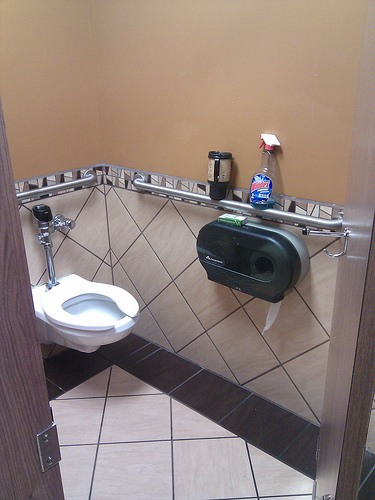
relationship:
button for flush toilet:
[32, 203, 52, 221] [29, 200, 139, 356]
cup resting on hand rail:
[207, 151, 235, 200] [133, 169, 341, 225]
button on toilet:
[32, 203, 52, 221] [29, 201, 139, 355]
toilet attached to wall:
[28, 272, 139, 354] [0, 0, 111, 402]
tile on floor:
[163, 367, 245, 424] [39, 331, 312, 498]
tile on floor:
[126, 345, 203, 390] [39, 331, 312, 498]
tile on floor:
[219, 392, 321, 479] [39, 331, 312, 498]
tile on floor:
[101, 329, 163, 369] [39, 331, 312, 498]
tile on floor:
[40, 347, 106, 392] [39, 331, 312, 498]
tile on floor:
[168, 392, 245, 439] [39, 331, 312, 498]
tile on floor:
[245, 439, 314, 496] [39, 331, 312, 498]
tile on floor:
[172, 437, 259, 499] [39, 331, 312, 498]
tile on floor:
[87, 437, 173, 497] [39, 331, 312, 498]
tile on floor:
[54, 441, 98, 498] [39, 331, 312, 498]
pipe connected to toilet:
[31, 214, 75, 284] [28, 272, 139, 354]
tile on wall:
[238, 363, 317, 422] [99, 168, 338, 431]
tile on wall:
[289, 235, 344, 337] [99, 168, 338, 431]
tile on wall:
[241, 288, 329, 365] [99, 168, 338, 431]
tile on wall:
[139, 199, 203, 278] [99, 168, 338, 431]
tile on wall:
[146, 280, 206, 352] [99, 168, 338, 431]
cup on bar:
[207, 151, 235, 200] [131, 176, 343, 232]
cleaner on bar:
[249, 128, 280, 210] [131, 176, 343, 232]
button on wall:
[32, 203, 53, 221] [0, 0, 114, 363]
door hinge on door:
[35, 422, 62, 471] [0, 106, 67, 496]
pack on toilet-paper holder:
[218, 213, 247, 227] [195, 217, 313, 303]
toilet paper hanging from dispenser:
[258, 295, 283, 334] [194, 214, 311, 301]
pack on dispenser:
[215, 210, 247, 224] [194, 214, 311, 301]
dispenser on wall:
[197, 216, 309, 305] [91, 2, 371, 455]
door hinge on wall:
[35, 422, 62, 471] [0, 80, 66, 495]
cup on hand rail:
[206, 150, 240, 206] [133, 173, 343, 231]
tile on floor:
[242, 435, 311, 499] [39, 331, 312, 498]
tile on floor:
[169, 396, 237, 436] [39, 331, 312, 498]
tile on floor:
[99, 392, 171, 443] [39, 331, 312, 498]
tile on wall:
[298, 235, 337, 336] [99, 168, 338, 431]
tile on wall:
[282, 336, 333, 423] [99, 168, 338, 431]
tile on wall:
[146, 274, 207, 355] [99, 168, 338, 431]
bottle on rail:
[246, 130, 288, 211] [131, 173, 341, 232]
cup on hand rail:
[207, 151, 235, 200] [133, 173, 343, 231]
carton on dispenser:
[216, 209, 246, 226] [195, 218, 309, 303]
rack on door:
[300, 223, 351, 257] [306, 2, 361, 495]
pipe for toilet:
[28, 206, 74, 286] [28, 272, 139, 354]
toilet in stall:
[28, 272, 139, 354] [4, 6, 348, 494]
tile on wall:
[198, 298, 288, 390] [86, 3, 346, 440]